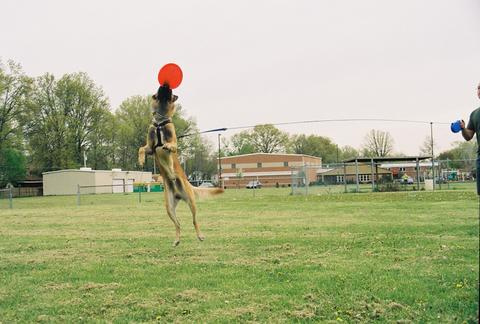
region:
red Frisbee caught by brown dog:
[144, 61, 194, 99]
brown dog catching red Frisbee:
[139, 64, 215, 257]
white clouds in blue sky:
[21, 16, 78, 51]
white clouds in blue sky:
[79, 2, 121, 37]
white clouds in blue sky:
[83, 32, 118, 59]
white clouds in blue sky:
[126, 25, 169, 49]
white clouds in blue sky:
[234, 22, 257, 60]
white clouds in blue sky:
[201, 20, 259, 92]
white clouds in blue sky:
[256, 14, 290, 51]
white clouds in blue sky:
[298, 10, 344, 77]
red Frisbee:
[152, 64, 193, 85]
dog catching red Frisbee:
[128, 72, 204, 231]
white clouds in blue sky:
[2, 8, 49, 42]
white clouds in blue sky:
[44, 11, 76, 55]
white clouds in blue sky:
[91, 11, 139, 39]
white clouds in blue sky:
[89, 47, 140, 80]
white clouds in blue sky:
[195, 16, 234, 63]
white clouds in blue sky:
[216, 74, 279, 108]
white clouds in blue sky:
[300, 41, 354, 95]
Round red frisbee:
[157, 59, 183, 89]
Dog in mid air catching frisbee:
[135, 57, 225, 251]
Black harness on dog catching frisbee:
[148, 119, 179, 152]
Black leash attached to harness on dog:
[172, 115, 447, 133]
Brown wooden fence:
[1, 186, 42, 199]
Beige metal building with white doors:
[38, 165, 153, 197]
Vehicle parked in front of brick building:
[243, 175, 264, 192]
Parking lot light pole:
[212, 130, 225, 187]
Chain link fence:
[289, 160, 359, 196]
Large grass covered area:
[221, 204, 440, 304]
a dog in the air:
[136, 82, 203, 251]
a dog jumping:
[130, 83, 205, 247]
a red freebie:
[151, 60, 190, 92]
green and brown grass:
[140, 253, 287, 300]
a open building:
[340, 153, 427, 191]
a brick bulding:
[214, 153, 302, 191]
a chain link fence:
[75, 179, 146, 205]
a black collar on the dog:
[149, 121, 171, 134]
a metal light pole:
[428, 121, 435, 176]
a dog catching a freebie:
[134, 57, 206, 260]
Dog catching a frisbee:
[137, 51, 219, 248]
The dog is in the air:
[115, 79, 215, 251]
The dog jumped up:
[126, 74, 213, 256]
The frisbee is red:
[141, 53, 198, 94]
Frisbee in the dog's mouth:
[131, 46, 200, 118]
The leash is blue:
[438, 116, 469, 144]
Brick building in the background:
[211, 151, 326, 192]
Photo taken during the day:
[4, 12, 468, 308]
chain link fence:
[15, 170, 458, 196]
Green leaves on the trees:
[2, 54, 202, 160]